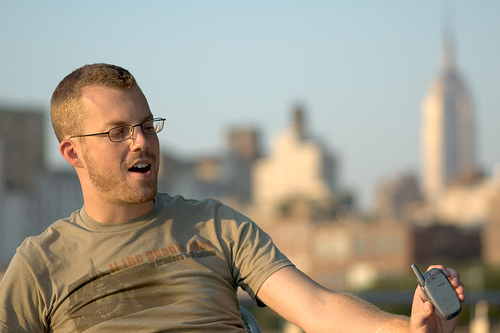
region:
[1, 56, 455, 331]
a man wearing glasses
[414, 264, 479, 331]
a hand holding a cell phone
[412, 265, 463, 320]
a small gray cell phone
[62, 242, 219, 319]
a logo on a tan t-shirt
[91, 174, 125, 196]
blond hair on a face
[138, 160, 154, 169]
white teeth in a mouth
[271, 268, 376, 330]
an arm extended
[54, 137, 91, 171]
an ear on a head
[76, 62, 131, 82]
short blond hair on a head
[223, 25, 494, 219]
a city in the background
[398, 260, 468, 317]
an old style flip phone cell phone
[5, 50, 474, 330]
a man holding a flip phone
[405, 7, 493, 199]
Empire State Building in the background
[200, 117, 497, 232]
cityscape in the background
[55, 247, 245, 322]
a logo on a cotton tshirt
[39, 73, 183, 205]
a man wearing glasses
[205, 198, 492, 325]
an arm extending and holding a cel phone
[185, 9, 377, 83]
a clear blue sky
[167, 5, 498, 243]
a view of New York City in the background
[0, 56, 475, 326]
young gentleman holding a flip phone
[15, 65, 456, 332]
man holding cell phone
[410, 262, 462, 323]
back of gray flip phone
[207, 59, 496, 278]
city skyline in background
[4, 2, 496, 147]
blue of daytime sky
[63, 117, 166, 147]
glasses on man's face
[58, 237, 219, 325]
image on front of shirt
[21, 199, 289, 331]
short sleeved tee shirt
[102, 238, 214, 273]
orange words on shirt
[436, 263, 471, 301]
fingers on side of phone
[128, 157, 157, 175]
teeth in open mouth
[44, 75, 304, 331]
the guy has glasses on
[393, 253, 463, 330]
the phone is silver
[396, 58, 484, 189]
th skycraper is the tallest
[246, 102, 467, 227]
the background is blurrry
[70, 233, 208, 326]
a picture is on the shirt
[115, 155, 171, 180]
the mouth is open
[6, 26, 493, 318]
the scene is outdoors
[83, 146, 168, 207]
the man has beards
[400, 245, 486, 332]
hand is holding a phone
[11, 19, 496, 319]
it is sunny outside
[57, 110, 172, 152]
man is wearing eye glasses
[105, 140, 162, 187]
man's mouth is open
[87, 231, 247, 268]
red letters on man's shirt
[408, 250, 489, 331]
man is holding a phone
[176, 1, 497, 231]
buildings behind the man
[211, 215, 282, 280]
the shirt is wrinkled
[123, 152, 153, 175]
man's teeth are showing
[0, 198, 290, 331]
man's shirt is brown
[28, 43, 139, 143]
man's hair is blonde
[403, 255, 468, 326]
the phone is gray